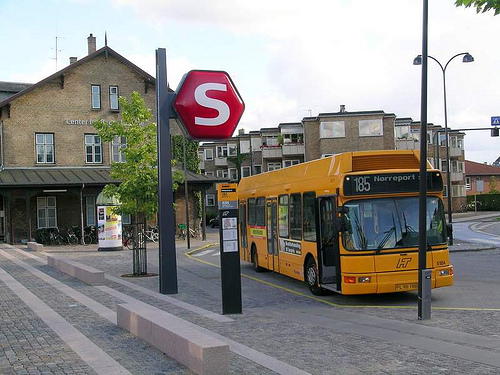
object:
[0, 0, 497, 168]
sky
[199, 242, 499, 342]
curb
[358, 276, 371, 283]
headlight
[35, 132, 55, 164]
window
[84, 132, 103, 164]
window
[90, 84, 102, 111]
window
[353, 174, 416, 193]
marquee display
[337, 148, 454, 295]
bus front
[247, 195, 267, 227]
windows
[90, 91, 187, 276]
tree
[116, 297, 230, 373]
stone slab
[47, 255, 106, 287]
stone slab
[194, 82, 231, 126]
letter s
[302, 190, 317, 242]
window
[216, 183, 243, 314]
post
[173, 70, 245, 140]
sign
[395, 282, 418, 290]
license plate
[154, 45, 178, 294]
pole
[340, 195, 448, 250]
front window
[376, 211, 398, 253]
windshield wipers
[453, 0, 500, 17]
leaves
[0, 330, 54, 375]
cobblestones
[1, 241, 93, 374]
ground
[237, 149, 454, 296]
bus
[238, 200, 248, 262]
door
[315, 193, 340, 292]
door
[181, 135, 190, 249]
pole